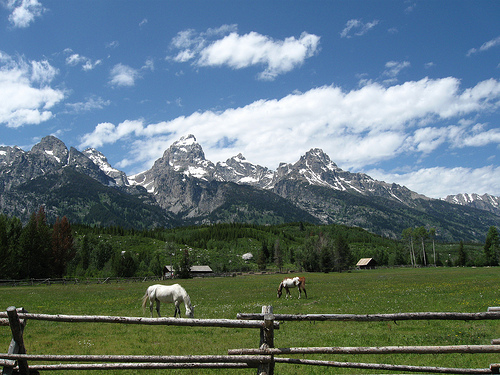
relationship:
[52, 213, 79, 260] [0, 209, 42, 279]
red tree among green trees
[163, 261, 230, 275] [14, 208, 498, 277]
house by trees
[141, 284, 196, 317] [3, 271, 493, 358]
horse eating grass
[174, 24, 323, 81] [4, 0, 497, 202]
cloud in sky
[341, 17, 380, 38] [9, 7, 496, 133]
cloud in sky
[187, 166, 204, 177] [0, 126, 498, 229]
snow on mountains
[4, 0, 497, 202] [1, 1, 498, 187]
sky with clouds